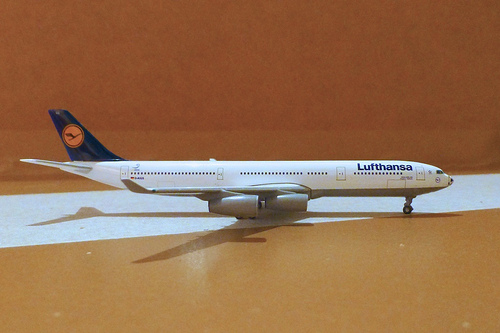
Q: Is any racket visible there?
A: No, there are no rackets.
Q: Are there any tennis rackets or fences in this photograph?
A: No, there are no tennis rackets or fences.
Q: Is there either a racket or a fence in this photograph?
A: No, there are no rackets or fences.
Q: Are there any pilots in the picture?
A: No, there are no pilots.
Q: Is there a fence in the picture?
A: No, there are no fences.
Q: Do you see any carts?
A: No, there are no carts.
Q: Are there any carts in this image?
A: No, there are no carts.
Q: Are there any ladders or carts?
A: No, there are no carts or ladders.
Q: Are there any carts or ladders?
A: No, there are no carts or ladders.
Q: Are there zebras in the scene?
A: No, there are no zebras.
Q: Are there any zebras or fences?
A: No, there are no zebras or fences.